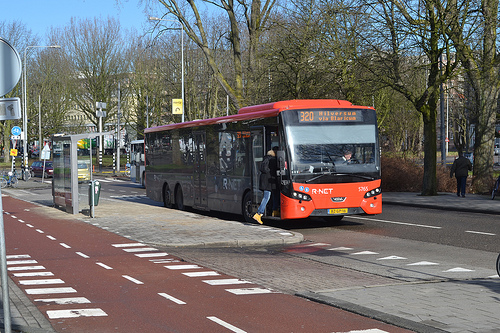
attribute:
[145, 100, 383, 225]
bus — silver, orange, stopped, orange and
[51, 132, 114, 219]
bus shelter — outdoors, metal, glass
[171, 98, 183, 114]
traffic sign — yellow, blue, white, black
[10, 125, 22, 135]
traffic sign — blue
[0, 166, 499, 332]
city street — paved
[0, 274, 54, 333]
sidewalk — brick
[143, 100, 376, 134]
roof — orange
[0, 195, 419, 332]
surface — red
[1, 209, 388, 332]
lines — white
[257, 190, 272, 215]
jeans — blue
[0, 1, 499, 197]
trees — bare